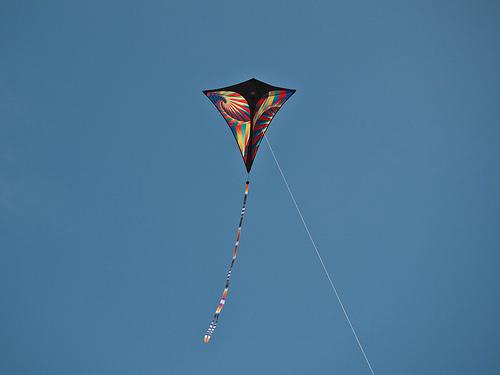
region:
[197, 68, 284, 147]
kite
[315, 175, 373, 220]
white clouds in blue sky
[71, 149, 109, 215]
white clouds in blue sky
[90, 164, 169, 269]
white clouds in blue sky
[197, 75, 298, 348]
multi colored kite with a tail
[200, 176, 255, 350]
long striped kite tail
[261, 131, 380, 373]
long thin white string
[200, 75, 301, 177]
diamond shaped colorful kite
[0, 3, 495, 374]
uniformly colored blue sky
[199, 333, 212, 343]
tip of the kite's tail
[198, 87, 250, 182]
swirly striped design on the left side of the kite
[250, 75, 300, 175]
swirly striped design on the right side of the kite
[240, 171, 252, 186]
string connecting the kite to its tail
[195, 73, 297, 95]
black tip of the kite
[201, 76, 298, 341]
Kite flying in the sky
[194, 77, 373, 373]
Kite flying on a string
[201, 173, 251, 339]
Red white and blue kite tail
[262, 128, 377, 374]
Long white kite string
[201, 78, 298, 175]
Triangular shaped kite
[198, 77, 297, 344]
Colorful triangular kite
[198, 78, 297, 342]
Kite with a tail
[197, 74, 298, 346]
Kite in a blue sky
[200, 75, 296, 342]
Black and colorful kite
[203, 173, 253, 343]
Long tail of a kite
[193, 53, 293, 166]
kite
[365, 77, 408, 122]
white clouds in blue sky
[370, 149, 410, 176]
white clouds in blue sky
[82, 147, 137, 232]
white clouds in blue sky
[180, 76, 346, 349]
A kite in the sky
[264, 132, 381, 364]
A white kite string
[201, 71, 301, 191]
A black kite with colored print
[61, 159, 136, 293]
A clear sky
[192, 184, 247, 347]
A kite tail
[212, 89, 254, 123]
A colored spiral shape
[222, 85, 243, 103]
A orange colored design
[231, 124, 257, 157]
Orange and green stipe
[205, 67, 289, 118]
Black diamond shape